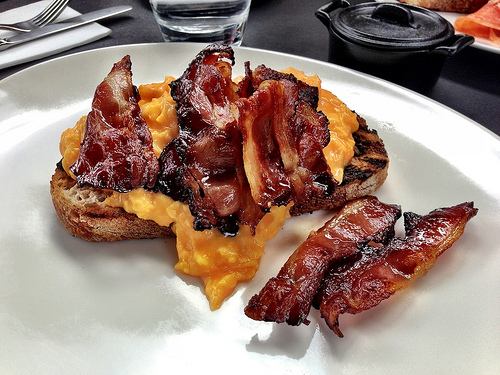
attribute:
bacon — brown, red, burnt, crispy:
[97, 67, 331, 206]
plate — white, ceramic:
[20, 62, 493, 357]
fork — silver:
[2, 0, 78, 36]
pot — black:
[316, 7, 460, 85]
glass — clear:
[150, 2, 245, 50]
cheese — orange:
[150, 206, 250, 305]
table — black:
[38, 11, 484, 81]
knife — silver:
[22, 10, 131, 54]